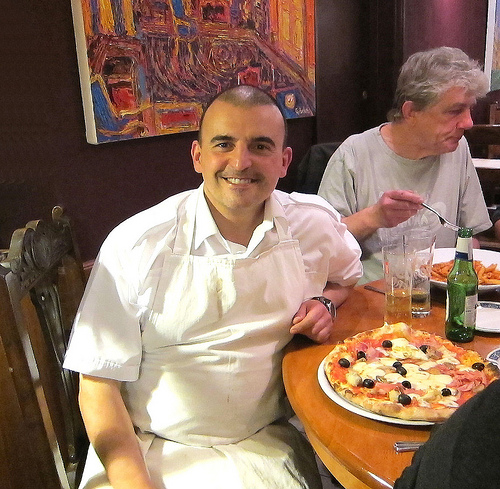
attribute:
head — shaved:
[196, 81, 281, 212]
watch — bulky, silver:
[312, 295, 337, 317]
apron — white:
[76, 190, 323, 487]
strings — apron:
[139, 189, 214, 254]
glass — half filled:
[380, 241, 410, 322]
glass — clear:
[377, 245, 417, 326]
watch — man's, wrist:
[320, 288, 340, 320]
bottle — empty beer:
[445, 227, 478, 344]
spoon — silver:
[409, 188, 498, 256]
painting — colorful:
[68, 2, 320, 140]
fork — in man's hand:
[423, 201, 461, 238]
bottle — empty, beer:
[439, 222, 482, 347]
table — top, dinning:
[345, 426, 407, 480]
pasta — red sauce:
[419, 258, 499, 284]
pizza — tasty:
[324, 319, 498, 429]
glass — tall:
[382, 230, 414, 329]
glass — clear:
[332, 212, 425, 319]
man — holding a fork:
[317, 44, 494, 271]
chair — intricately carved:
[11, 175, 198, 487]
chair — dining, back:
[2, 198, 121, 487]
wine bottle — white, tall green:
[443, 226, 479, 343]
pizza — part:
[360, 332, 457, 407]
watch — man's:
[305, 292, 340, 320]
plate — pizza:
[318, 326, 484, 417]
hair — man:
[394, 45, 484, 115]